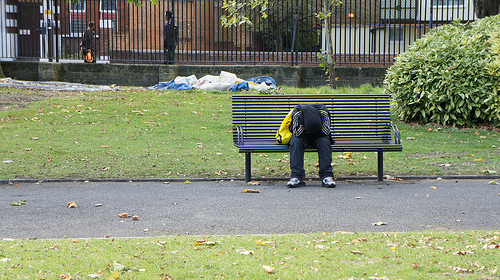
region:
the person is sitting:
[230, 69, 382, 201]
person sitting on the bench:
[222, 87, 369, 200]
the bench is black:
[165, 65, 410, 195]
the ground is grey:
[194, 172, 416, 232]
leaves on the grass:
[328, 232, 498, 278]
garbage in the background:
[142, 61, 278, 100]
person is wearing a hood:
[235, 96, 340, 148]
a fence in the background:
[132, 0, 390, 92]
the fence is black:
[145, 0, 382, 92]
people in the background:
[51, 3, 193, 58]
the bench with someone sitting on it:
[230, 93, 403, 188]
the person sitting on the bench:
[275, 104, 336, 187]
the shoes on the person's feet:
[285, 176, 336, 187]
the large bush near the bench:
[382, 14, 498, 131]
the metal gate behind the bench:
[0, 0, 498, 64]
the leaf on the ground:
[241, 187, 260, 194]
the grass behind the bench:
[0, 84, 498, 177]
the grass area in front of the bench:
[0, 229, 499, 279]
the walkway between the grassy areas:
[0, 174, 499, 239]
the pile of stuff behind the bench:
[147, 70, 278, 92]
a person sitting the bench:
[258, 87, 343, 197]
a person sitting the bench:
[210, 63, 407, 197]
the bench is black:
[223, 88, 407, 168]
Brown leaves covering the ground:
[239, 244, 282, 279]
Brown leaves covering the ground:
[311, 229, 354, 266]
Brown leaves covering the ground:
[430, 255, 461, 276]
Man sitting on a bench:
[269, 94, 349, 204]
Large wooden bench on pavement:
[205, 69, 409, 181]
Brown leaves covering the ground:
[8, 142, 105, 190]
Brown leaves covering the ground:
[97, 144, 135, 183]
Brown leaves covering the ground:
[130, 139, 192, 181]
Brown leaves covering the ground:
[173, 130, 249, 190]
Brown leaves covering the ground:
[410, 139, 493, 180]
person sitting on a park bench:
[286, 103, 336, 188]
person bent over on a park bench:
[286, 105, 333, 190]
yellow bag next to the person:
[274, 110, 298, 142]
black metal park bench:
[232, 93, 402, 179]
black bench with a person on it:
[230, 93, 400, 183]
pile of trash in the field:
[148, 68, 275, 93]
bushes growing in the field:
[383, 15, 499, 122]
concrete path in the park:
[1, 171, 499, 238]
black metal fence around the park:
[1, 0, 497, 61]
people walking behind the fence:
[79, 8, 184, 61]